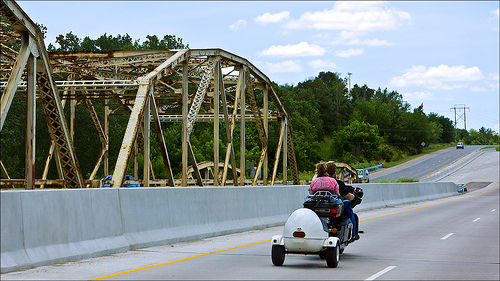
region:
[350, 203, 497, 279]
Paint lane divide indicator on road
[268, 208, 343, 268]
Two wheel motorcycle trailer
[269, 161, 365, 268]
Two people on motorcycle with trailer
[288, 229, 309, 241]
Red tail light on trailer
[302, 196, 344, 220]
Storage bin on motorcycle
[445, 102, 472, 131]
Electric power utility pole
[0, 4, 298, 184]
Metal trestle of bridge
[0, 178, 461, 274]
Cement divider barrier on highway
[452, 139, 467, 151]
Car driving on roadway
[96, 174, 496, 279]
Painted highway shoulder boundary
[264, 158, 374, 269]
Couple riding a motorcycle with a career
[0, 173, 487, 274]
Concrete partition in the highway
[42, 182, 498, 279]
Road with yellow and white markings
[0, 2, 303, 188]
Web of steel structures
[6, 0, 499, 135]
Sky with sparse clouds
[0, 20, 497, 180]
Thick green bushes of trees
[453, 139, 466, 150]
Car driving on the road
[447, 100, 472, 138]
Structure to hold power cables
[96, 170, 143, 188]
Blue vehicle of the road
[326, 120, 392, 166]
Short tree on the road side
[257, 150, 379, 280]
A motorcyle towing a storage unit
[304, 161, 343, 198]
A woman in a pink blouse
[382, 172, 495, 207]
Divider in the middle of a highway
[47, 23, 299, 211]
Portion of an old-time bridge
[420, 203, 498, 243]
Paintmarks designating lanes on a highway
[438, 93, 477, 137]
A distant power pole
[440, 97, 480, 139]
A distant electrical pole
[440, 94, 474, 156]
A car and a power pole in the distance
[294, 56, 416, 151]
A utility pole behind trees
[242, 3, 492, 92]
Cumulus clouds in a distant sky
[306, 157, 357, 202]
two people riding one motorcycle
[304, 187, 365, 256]
motorcycle hooked up to trailer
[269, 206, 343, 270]
trailer hooked up to motorcycle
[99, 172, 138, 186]
car travelling on bridge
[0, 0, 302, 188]
road bridge made of steel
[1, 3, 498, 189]
whole bunch of trees lining the road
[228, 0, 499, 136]
whole bunch of clouds in sky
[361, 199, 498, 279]
white dashes on street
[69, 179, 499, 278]
yellow boundary markers on street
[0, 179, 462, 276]
concrete pillars for road division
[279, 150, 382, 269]
Two people on motored bike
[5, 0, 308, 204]
Rusted bridge in the background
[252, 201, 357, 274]
Attachment pod on bike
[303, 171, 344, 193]
Person wearing pink shirt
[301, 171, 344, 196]
Pink tee shirt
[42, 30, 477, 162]
Green forest next to highway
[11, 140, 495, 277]
Large highway with numerous lanes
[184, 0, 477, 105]
White fluffy clouds in the sky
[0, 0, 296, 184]
Small rusted bridge on highway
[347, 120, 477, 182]
Cars in opposite traffic